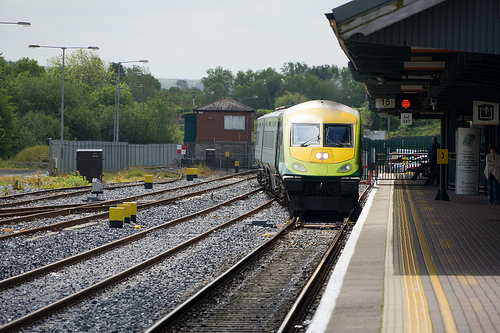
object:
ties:
[281, 210, 350, 333]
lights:
[28, 44, 100, 142]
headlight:
[292, 162, 308, 173]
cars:
[385, 148, 431, 174]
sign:
[375, 97, 397, 108]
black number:
[381, 98, 389, 105]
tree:
[0, 109, 72, 167]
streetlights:
[26, 44, 100, 51]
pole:
[58, 48, 70, 137]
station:
[325, 0, 500, 192]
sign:
[436, 147, 448, 163]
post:
[433, 143, 449, 201]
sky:
[0, 1, 355, 78]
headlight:
[336, 162, 355, 174]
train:
[251, 99, 361, 216]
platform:
[317, 158, 496, 330]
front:
[282, 97, 362, 182]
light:
[400, 98, 410, 109]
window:
[289, 122, 322, 148]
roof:
[323, 0, 500, 56]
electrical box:
[75, 149, 106, 185]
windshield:
[291, 124, 352, 148]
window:
[322, 122, 354, 148]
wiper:
[300, 134, 320, 147]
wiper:
[326, 136, 345, 147]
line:
[399, 170, 462, 331]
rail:
[0, 167, 367, 331]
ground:
[2, 165, 371, 333]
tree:
[132, 96, 188, 146]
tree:
[199, 63, 236, 106]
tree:
[230, 65, 283, 110]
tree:
[122, 64, 162, 105]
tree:
[44, 43, 111, 110]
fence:
[362, 140, 444, 180]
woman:
[484, 144, 500, 208]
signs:
[400, 114, 413, 123]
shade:
[390, 178, 485, 276]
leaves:
[87, 49, 97, 60]